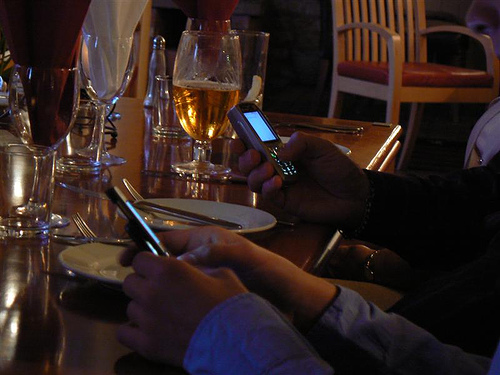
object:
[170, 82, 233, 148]
wine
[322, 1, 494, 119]
chair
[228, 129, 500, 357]
man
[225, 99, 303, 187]
phone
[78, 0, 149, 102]
napkin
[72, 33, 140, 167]
glass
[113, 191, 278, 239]
plate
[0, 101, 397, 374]
table